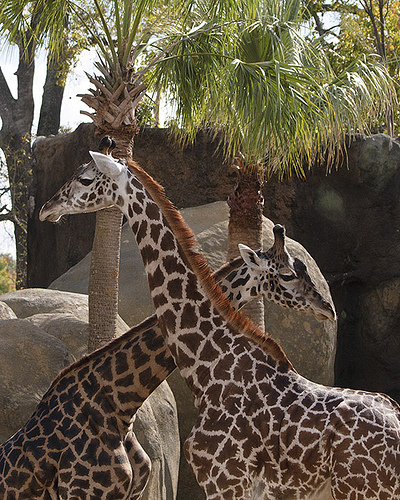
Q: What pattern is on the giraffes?
A: Spots.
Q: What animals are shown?
A: Giraffes.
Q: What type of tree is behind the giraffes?
A: Palm tree.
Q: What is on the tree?
A: Leaves.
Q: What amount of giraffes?
A: Two.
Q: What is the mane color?
A: Brown.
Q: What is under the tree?
A: Giraffe.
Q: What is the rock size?
A: Large.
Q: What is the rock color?
A: Gray.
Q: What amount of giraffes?
A: Two.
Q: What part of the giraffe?
A: Neck.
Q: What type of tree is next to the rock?
A: Palm.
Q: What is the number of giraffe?
A: Two.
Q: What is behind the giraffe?
A: Tree.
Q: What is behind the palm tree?
A: Rock.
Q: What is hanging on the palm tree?
A: Leaves.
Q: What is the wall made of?
A: Rock.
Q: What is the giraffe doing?
A: Standing.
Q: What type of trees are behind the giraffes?
A: Palm trees.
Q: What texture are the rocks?
A: Smooth.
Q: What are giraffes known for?
A: Long necks.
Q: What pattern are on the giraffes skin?
A: Spots.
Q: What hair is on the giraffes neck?
A: A mane.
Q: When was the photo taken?
A: Daytime.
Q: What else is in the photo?
A: Trees.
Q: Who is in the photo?
A: No one.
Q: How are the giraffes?
A: Standing.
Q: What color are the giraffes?
A: Brown.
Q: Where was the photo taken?
A: At a zoo.